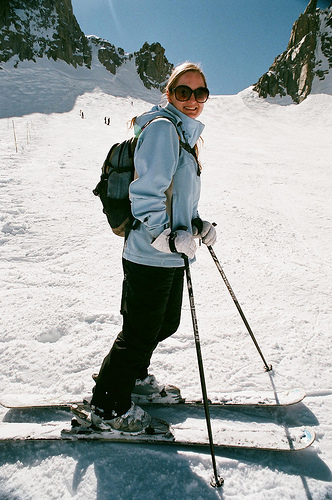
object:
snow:
[312, 26, 332, 96]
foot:
[91, 403, 170, 434]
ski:
[1, 422, 315, 451]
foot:
[132, 375, 182, 401]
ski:
[0, 391, 306, 410]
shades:
[172, 85, 210, 104]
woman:
[92, 62, 217, 436]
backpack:
[93, 137, 138, 237]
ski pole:
[169, 226, 224, 488]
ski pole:
[204, 217, 274, 374]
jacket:
[122, 106, 206, 270]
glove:
[151, 227, 198, 260]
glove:
[201, 221, 218, 247]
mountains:
[254, 0, 331, 105]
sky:
[71, 1, 284, 63]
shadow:
[73, 441, 220, 499]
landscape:
[0, 1, 331, 500]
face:
[171, 71, 207, 120]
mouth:
[183, 105, 198, 112]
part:
[103, 197, 132, 236]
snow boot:
[92, 403, 169, 438]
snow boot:
[131, 375, 181, 406]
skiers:
[81, 110, 85, 119]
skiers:
[104, 116, 107, 124]